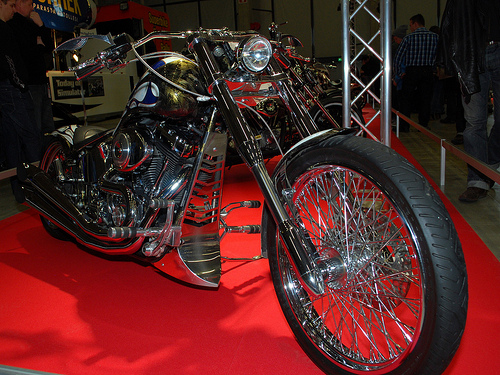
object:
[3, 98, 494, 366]
platform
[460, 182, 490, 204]
black shoe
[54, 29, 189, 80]
metal handle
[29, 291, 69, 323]
red surface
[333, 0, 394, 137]
beams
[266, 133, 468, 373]
front tire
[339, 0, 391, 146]
pillar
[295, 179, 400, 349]
silver spokes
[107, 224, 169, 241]
stand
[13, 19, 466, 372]
bike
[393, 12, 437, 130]
man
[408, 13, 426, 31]
head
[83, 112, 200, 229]
engine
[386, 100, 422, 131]
rails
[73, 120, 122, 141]
seat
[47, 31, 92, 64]
mirror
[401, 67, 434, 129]
pants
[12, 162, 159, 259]
exhaust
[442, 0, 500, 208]
man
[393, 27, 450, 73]
shirt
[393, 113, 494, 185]
railing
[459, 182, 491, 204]
foot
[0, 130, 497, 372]
carpet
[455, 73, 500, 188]
pants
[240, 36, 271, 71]
headlight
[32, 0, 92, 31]
sign